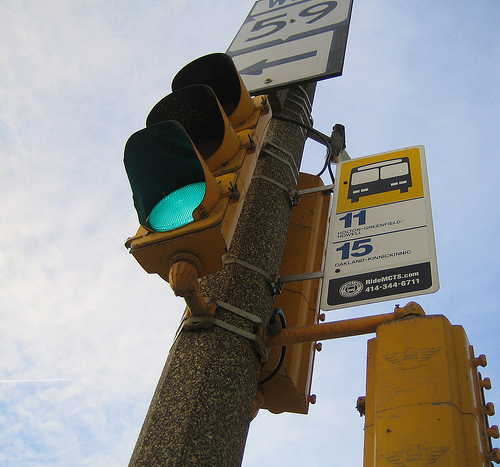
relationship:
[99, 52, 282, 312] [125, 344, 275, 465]
traffic light attached to pole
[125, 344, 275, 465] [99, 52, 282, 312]
pole with a traffic light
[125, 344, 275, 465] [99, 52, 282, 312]
pole with traffic light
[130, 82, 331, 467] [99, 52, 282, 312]
pole with traffic light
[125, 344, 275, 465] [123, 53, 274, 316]
pole with traffic light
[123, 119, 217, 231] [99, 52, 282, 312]
covers over traffic light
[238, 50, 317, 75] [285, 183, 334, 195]
arrow on bar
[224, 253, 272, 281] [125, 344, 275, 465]
bracket around pole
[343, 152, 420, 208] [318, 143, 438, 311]
bus icon on sign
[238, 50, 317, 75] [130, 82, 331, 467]
arrow on pole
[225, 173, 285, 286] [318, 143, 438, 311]
straps hold sign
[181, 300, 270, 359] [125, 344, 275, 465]
bands around pole